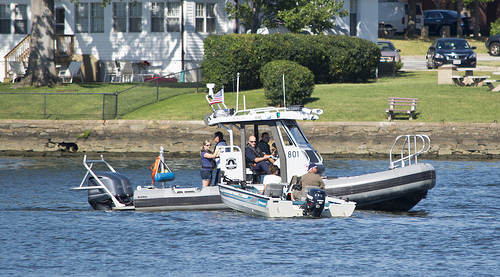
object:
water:
[0, 151, 498, 277]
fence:
[0, 66, 209, 121]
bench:
[385, 98, 420, 123]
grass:
[140, 60, 500, 120]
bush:
[258, 60, 315, 106]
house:
[0, 0, 377, 83]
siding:
[111, 36, 183, 60]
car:
[425, 37, 477, 69]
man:
[243, 136, 279, 177]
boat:
[216, 179, 357, 219]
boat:
[69, 106, 435, 220]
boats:
[69, 106, 437, 222]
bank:
[0, 90, 499, 154]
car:
[420, 8, 465, 35]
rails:
[0, 34, 79, 84]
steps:
[19, 54, 33, 77]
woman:
[201, 139, 213, 187]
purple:
[198, 148, 219, 172]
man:
[294, 163, 327, 204]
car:
[378, 40, 402, 71]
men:
[255, 131, 280, 173]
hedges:
[198, 31, 381, 85]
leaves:
[232, 1, 349, 28]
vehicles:
[378, 0, 425, 38]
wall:
[0, 117, 499, 157]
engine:
[297, 186, 332, 217]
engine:
[87, 167, 131, 213]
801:
[285, 150, 303, 159]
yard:
[0, 55, 203, 118]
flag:
[205, 87, 229, 109]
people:
[197, 131, 325, 200]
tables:
[452, 69, 498, 93]